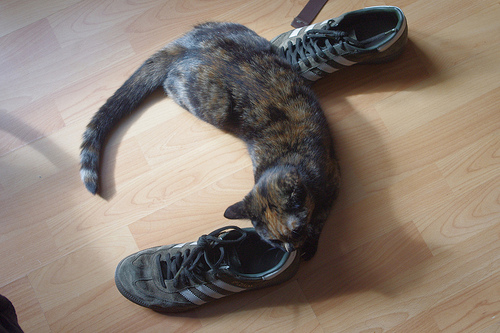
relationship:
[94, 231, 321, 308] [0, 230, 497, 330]
shoe on floor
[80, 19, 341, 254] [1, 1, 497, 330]
cat playing with shoe on floor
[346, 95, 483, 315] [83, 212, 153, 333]
floor made of wood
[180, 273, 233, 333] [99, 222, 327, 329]
stripes on a sneaker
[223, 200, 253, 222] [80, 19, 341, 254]
ear on a cat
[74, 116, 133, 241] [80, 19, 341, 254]
tail of a cat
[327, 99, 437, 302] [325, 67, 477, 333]
shadows on floor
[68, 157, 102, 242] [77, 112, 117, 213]
end of cat tail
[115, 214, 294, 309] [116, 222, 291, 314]
top of sneaker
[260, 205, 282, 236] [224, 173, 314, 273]
gold patch on cats head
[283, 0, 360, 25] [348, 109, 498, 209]
strap on floor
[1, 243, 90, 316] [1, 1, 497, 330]
pattern on floor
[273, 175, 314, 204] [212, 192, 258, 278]
left ear on cat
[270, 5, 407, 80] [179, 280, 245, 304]
shoe with white stripes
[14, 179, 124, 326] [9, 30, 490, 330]
different shades of brown on a wood floor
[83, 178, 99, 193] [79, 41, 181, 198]
stripe on end of cats tail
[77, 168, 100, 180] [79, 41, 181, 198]
stripe on end of cats tail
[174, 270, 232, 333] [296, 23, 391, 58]
strpes on side of shoe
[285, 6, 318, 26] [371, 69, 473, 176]
strap on floor